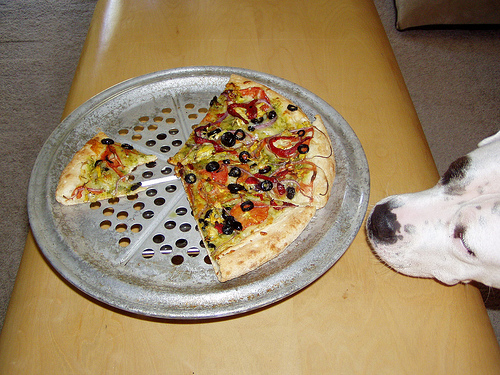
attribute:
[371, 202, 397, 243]
nose — black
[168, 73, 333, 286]
pieces — pizza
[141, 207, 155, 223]
holes — circular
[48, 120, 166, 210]
pizza — half-eaten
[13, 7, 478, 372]
surface — tan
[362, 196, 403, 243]
nose — black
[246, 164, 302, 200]
olives — black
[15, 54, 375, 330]
plate — metallic 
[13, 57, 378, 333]
tray — silver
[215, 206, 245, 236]
olives — black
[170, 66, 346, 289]
pizza — sliced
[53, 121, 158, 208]
pizza — half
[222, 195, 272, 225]
tomato — red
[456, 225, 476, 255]
eyes — closed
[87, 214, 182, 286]
tray — silver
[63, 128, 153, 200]
pizza — cut, half eaten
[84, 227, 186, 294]
tray — silver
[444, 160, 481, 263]
eyes — closed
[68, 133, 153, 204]
pizza — eaten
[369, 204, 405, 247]
nose — black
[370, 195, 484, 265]
dog —  white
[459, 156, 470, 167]
fur — black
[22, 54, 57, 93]
carpet — beige